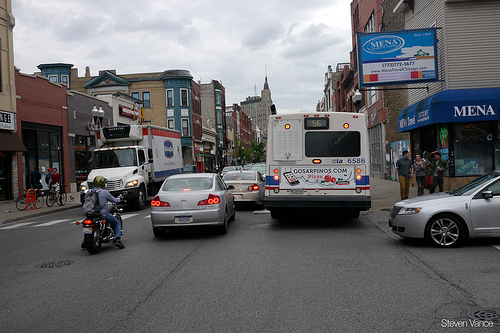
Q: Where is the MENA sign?
A: On the right.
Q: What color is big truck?
A: Red white blue.